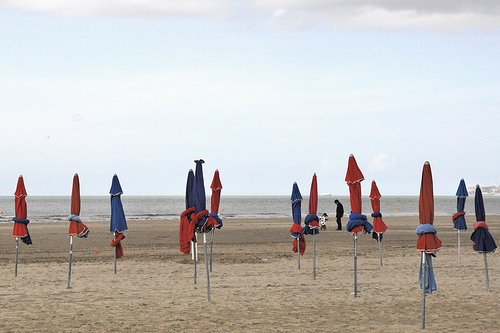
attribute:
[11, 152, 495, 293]
umbrellas — empty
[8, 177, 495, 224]
surf — very calm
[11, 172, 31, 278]
umbrella — red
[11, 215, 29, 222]
strap — blue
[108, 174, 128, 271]
umbrella — blue 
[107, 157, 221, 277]
ties — red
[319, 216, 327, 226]
coat — white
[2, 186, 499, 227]
sea — grey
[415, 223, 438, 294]
tie — blue, red 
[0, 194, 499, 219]
water — calm , blue , gray 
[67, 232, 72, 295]
silver pole — tall 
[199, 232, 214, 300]
silver pole — tall 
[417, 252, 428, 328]
silver pole — tall 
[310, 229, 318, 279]
silver pole — tall 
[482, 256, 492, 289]
silver pole — tall 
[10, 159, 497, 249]
umbrellas — metal posts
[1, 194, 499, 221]
ocean — calm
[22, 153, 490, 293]
folded umbrellas — on the beach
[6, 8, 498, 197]
sky — light , blue 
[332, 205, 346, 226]
clothes — black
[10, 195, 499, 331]
beach — brown, sandy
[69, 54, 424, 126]
clouds — wispy , white 